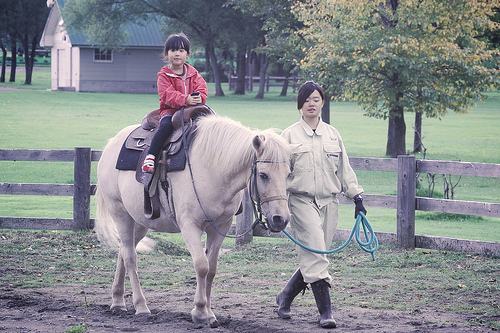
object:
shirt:
[277, 115, 366, 209]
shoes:
[139, 152, 158, 173]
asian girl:
[136, 33, 208, 173]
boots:
[307, 275, 337, 328]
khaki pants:
[285, 194, 344, 288]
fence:
[0, 145, 500, 259]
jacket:
[155, 62, 210, 119]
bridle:
[247, 146, 269, 226]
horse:
[95, 112, 313, 328]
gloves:
[351, 195, 371, 220]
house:
[39, 0, 185, 94]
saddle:
[115, 99, 217, 219]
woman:
[274, 81, 367, 327]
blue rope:
[280, 210, 381, 261]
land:
[0, 52, 500, 332]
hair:
[189, 113, 295, 182]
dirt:
[0, 228, 500, 332]